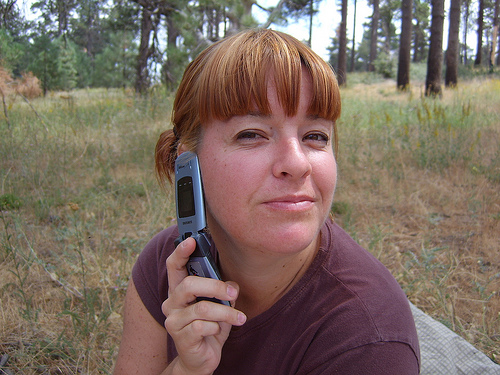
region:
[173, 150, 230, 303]
grey and black flip phone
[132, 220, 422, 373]
maroon cotton tee shirt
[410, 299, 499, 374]
grey wood park bench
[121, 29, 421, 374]
girl talking on phone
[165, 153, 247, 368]
cell phone in hand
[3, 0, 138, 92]
trees with green leaves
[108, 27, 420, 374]
girl sitting on bench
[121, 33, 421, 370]
girl sitting in park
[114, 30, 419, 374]
girl with red hair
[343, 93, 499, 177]
brown weeds in grass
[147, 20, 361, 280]
woman with red hair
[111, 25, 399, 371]
woman wearing brown t-shirt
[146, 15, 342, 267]
woman with hair in ponytail and fringe bangs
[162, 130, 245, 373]
flip-phone in woman's right hand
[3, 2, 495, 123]
trees in the woods beyond the clearing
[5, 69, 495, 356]
long grasses and wildflowers in the clearing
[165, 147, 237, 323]
silver flip-phone style cell phone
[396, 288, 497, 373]
wooden log on the ground behind the woman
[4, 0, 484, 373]
woman in a wooded park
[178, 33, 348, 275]
sunlight falls on the woman's face on her left side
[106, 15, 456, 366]
woman wearing purple shirt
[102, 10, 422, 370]
woman holding a phone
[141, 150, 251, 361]
cell phone in a woman hand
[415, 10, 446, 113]
tree trunk in woods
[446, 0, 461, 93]
tree trunk in woods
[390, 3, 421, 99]
tree trunk in woods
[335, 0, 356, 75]
tree trunk in woods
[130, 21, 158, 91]
tree trunk in woods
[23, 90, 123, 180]
green grass in woods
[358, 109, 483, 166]
green grass in woods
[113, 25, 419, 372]
A woman holding a cellphone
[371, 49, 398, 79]
A small full bush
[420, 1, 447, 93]
A large tree trunk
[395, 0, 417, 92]
A large tree trunk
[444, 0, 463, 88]
A large tree trunk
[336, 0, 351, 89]
A large tree trunk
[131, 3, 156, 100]
A large tree trunk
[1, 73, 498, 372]
A large grassy landscape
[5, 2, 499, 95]
A large wooded area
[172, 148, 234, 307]
A grey and black cellphone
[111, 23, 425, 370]
Red haired woman holding phone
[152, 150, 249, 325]
Silver blue flip style phone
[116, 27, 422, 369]
Smiling woman wearing a purple shirt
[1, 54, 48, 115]
Brown, dry looking shrub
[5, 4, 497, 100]
Green and brown trees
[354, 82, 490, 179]
Long yellow grass with flowers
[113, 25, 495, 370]
Woman sitting on a white and gray sheet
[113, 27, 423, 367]
Woman smiling while talking on the phone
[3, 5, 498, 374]
Trees and grass in a forest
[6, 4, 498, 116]
Hazy gray sky behind pine trees